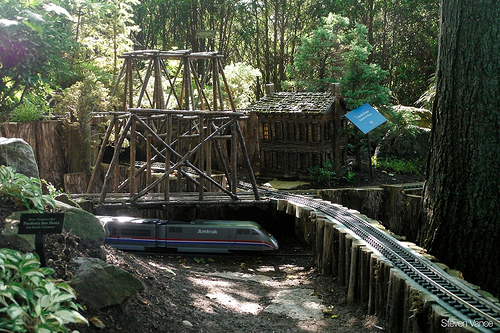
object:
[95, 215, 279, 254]
train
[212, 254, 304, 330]
dirt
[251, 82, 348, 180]
house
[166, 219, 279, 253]
section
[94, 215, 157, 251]
section